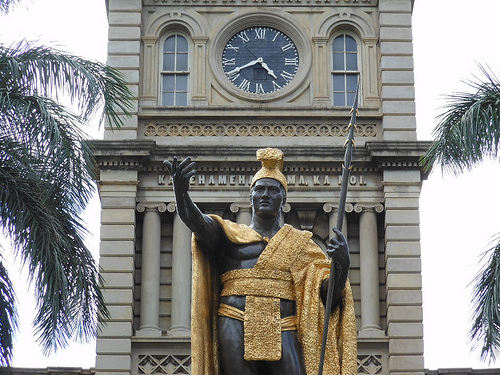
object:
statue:
[162, 77, 360, 375]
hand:
[162, 156, 197, 192]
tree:
[1, 39, 142, 375]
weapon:
[316, 73, 360, 375]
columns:
[136, 201, 167, 337]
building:
[82, 0, 441, 375]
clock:
[221, 26, 299, 95]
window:
[156, 30, 195, 110]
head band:
[249, 147, 288, 196]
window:
[330, 28, 363, 107]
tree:
[413, 64, 499, 361]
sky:
[2, 1, 108, 65]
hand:
[226, 56, 263, 76]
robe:
[189, 213, 357, 375]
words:
[158, 175, 367, 186]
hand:
[258, 57, 278, 80]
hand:
[326, 227, 351, 269]